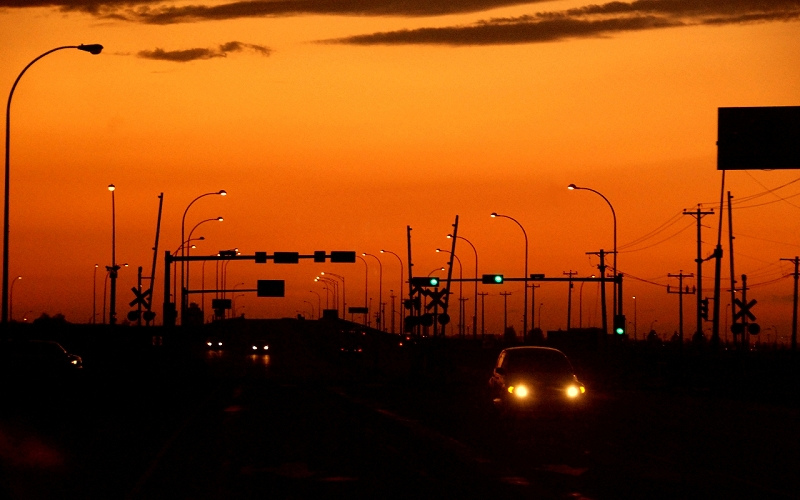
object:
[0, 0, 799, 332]
sky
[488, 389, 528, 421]
tire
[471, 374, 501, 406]
tire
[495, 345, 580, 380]
windshield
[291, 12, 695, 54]
clouds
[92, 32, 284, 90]
clouds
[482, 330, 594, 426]
vehicle